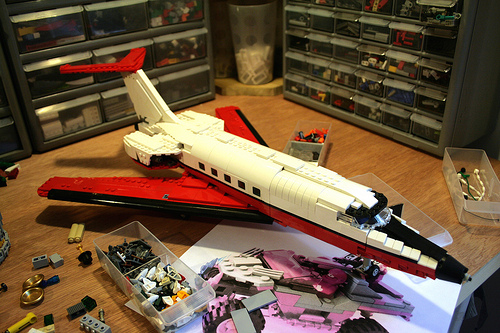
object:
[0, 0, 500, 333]
plane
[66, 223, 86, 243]
piece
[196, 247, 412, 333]
vehicle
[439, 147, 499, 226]
box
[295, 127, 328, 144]
lego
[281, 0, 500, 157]
shelve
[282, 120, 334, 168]
container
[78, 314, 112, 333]
hole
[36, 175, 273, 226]
wing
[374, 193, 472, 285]
nose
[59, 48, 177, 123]
tail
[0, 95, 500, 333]
desk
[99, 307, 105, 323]
brick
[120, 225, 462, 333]
paper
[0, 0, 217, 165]
cabinet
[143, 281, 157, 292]
block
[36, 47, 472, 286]
toy